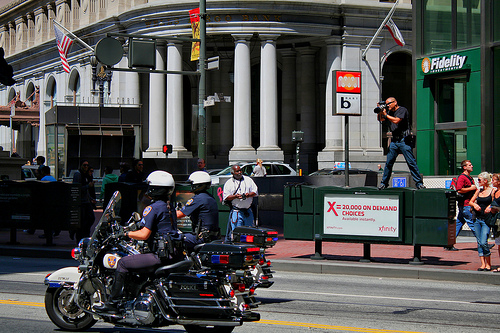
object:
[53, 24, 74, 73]
flag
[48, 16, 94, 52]
pole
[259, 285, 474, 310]
white line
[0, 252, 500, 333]
road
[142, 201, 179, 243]
shirt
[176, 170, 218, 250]
police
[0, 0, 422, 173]
building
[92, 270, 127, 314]
boots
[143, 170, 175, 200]
helmet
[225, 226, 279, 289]
motorcycle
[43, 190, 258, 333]
motorcycle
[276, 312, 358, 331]
yellow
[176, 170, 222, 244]
officer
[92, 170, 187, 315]
officer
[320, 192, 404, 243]
xfinity poster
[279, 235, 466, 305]
street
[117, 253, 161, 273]
pants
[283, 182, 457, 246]
black tank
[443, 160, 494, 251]
person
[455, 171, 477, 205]
shirt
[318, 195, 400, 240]
sign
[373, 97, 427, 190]
man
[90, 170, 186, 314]
police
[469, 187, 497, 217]
tank top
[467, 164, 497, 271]
woman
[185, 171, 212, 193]
helmet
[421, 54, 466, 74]
name